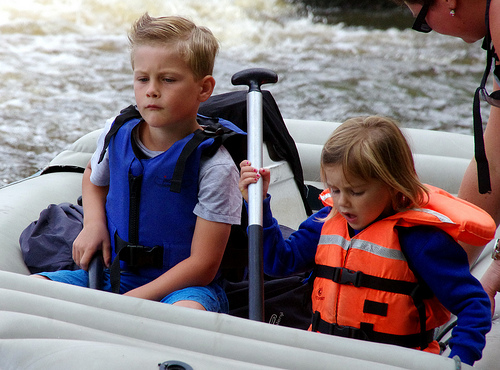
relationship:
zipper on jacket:
[126, 166, 140, 245] [91, 105, 247, 287]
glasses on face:
[414, 9, 452, 40] [419, 0, 464, 30]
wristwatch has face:
[488, 237, 498, 268] [490, 237, 499, 265]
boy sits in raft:
[27, 12, 244, 313] [1, 116, 496, 367]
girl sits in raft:
[0, 115, 498, 367] [1, 116, 496, 367]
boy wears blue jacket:
[27, 12, 244, 313] [103, 117, 249, 292]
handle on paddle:
[229, 65, 280, 93] [228, 65, 280, 325]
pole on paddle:
[246, 91, 268, 322] [228, 65, 280, 325]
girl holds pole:
[235, 115, 497, 366] [227, 60, 277, 319]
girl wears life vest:
[235, 115, 497, 366] [299, 172, 494, 350]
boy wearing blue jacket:
[27, 12, 244, 313] [103, 117, 249, 292]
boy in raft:
[27, 12, 244, 313] [36, 263, 288, 364]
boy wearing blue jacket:
[27, 12, 244, 313] [103, 117, 220, 292]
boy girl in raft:
[86, 12, 475, 369] [10, 301, 176, 367]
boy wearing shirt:
[27, 12, 244, 313] [87, 130, 244, 283]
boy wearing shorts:
[27, 12, 244, 313] [39, 264, 228, 313]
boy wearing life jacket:
[27, 12, 244, 313] [93, 109, 251, 290]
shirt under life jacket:
[87, 130, 244, 283] [93, 109, 251, 290]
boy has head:
[27, 12, 244, 313] [128, 10, 218, 130]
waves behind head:
[290, 24, 472, 116] [128, 10, 218, 130]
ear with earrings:
[442, 2, 461, 21] [444, 3, 459, 18]